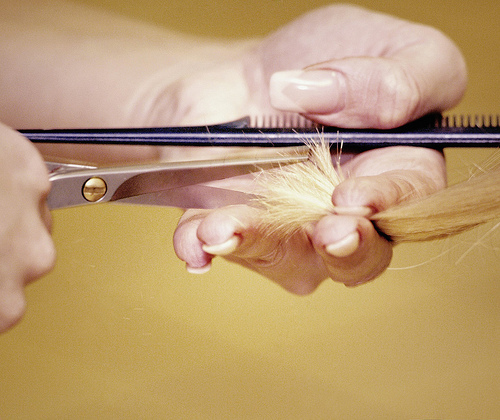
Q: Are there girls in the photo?
A: No, there are no girls.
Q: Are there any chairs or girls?
A: No, there are no girls or chairs.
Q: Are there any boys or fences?
A: No, there are no fences or boys.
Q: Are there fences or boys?
A: No, there are no fences or boys.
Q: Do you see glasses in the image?
A: No, there are no glasses.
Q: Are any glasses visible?
A: No, there are no glasses.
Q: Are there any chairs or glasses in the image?
A: No, there are no glasses or chairs.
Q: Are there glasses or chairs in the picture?
A: No, there are no glasses or chairs.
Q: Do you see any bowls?
A: No, there are no bowls.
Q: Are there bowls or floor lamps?
A: No, there are no bowls or floor lamps.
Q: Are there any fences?
A: No, there are no fences.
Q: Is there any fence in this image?
A: No, there are no fences.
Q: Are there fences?
A: No, there are no fences.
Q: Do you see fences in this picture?
A: No, there are no fences.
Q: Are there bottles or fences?
A: No, there are no fences or bottles.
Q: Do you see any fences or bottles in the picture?
A: No, there are no fences or bottles.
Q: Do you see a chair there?
A: No, there are no chairs.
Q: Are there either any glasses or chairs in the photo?
A: No, there are no chairs or glasses.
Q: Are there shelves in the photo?
A: No, there are no shelves.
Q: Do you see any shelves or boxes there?
A: No, there are no shelves or boxes.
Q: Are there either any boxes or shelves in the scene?
A: No, there are no shelves or boxes.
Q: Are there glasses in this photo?
A: No, there are no glasses.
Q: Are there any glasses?
A: No, there are no glasses.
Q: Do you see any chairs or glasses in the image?
A: No, there are no glasses or chairs.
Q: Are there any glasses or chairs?
A: No, there are no glasses or chairs.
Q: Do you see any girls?
A: No, there are no girls.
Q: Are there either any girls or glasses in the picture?
A: No, there are no girls or glasses.